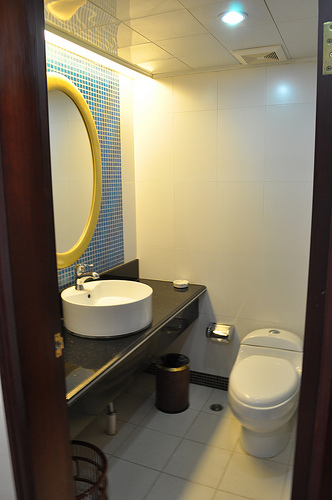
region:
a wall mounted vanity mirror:
[46, 70, 101, 269]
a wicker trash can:
[72, 437, 108, 498]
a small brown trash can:
[153, 351, 189, 414]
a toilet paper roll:
[204, 320, 232, 343]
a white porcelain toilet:
[226, 326, 300, 456]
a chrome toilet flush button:
[267, 328, 279, 335]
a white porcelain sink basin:
[61, 279, 151, 335]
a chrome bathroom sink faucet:
[73, 262, 98, 289]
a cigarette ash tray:
[172, 277, 188, 288]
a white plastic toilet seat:
[229, 353, 297, 406]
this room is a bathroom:
[51, 35, 288, 492]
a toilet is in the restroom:
[225, 317, 298, 454]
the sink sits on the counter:
[62, 264, 153, 336]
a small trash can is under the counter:
[154, 351, 191, 417]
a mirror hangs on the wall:
[42, 76, 103, 269]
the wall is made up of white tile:
[144, 95, 308, 320]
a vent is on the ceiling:
[223, 38, 287, 73]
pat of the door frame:
[0, 2, 68, 493]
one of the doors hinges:
[318, 16, 330, 83]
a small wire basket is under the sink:
[77, 438, 106, 498]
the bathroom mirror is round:
[47, 67, 106, 270]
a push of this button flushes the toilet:
[266, 327, 281, 335]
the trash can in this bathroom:
[152, 349, 194, 415]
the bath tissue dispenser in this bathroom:
[202, 318, 236, 344]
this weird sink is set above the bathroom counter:
[59, 261, 157, 341]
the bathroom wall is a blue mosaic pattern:
[47, 43, 127, 289]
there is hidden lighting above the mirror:
[44, 23, 157, 86]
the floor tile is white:
[71, 378, 289, 497]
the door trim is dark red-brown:
[1, 0, 79, 498]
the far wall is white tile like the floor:
[136, 79, 315, 365]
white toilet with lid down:
[223, 324, 308, 462]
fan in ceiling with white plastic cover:
[225, 41, 293, 68]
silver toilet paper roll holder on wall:
[200, 319, 235, 346]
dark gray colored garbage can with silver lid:
[149, 349, 195, 416]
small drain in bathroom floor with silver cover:
[204, 398, 224, 416]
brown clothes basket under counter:
[67, 431, 114, 498]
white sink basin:
[59, 279, 156, 341]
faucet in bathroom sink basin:
[69, 260, 102, 294]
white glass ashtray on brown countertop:
[171, 277, 191, 292]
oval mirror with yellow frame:
[38, 65, 110, 273]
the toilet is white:
[230, 320, 300, 463]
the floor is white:
[142, 426, 219, 483]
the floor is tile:
[121, 453, 200, 498]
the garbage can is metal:
[156, 347, 191, 416]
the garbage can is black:
[150, 343, 194, 419]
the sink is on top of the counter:
[66, 270, 159, 339]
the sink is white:
[61, 258, 148, 344]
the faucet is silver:
[74, 255, 97, 286]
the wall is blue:
[95, 201, 116, 249]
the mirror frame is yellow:
[76, 85, 103, 253]